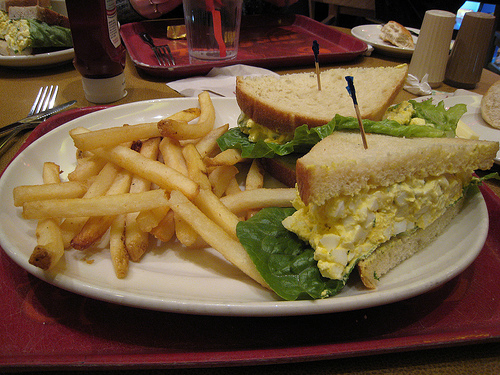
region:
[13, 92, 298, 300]
a pile of fries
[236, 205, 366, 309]
green leaf sticking out of the sandwich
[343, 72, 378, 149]
toothpick sticking in the bread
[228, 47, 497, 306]
two halves of a sandwich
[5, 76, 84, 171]
a fork and a knife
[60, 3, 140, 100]
bottle of ketchup on the table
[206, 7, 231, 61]
straw in the grass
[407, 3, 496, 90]
salt and pepper shakers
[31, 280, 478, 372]
shadow from the plate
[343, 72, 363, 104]
top of the toothpick is blue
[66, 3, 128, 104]
Plastic bottle of ketchup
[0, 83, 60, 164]
Silver fork on underneath knife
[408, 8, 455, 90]
Salt shaker on table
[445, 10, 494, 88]
Pepper shaker on table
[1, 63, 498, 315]
White plate with sandwich and fries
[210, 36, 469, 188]
Egg salad sandwich with toothpick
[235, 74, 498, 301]
Egg salad sandwich with toothpick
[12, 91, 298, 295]
Pile of french fries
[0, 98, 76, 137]
Silver butter knife on top of fork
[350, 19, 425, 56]
White plate with bread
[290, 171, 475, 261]
egg inside sandwich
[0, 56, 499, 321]
sandwiches on white dish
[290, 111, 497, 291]
the sandwich is triangle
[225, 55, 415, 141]
the sandwich is triangle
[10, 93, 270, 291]
french fries on white dish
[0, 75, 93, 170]
fork and knife on side a dish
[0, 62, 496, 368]
white dish on a tray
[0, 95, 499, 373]
tray is color red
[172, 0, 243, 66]
a glass on a tray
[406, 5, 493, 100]
bottles of salt and pepper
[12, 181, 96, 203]
french fry next to french fry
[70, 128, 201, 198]
french fry next to french fry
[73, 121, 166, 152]
french fry next to french fry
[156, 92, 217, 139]
french fry next to french fry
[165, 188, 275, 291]
french fry next to french fry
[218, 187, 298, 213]
french fry next to french fry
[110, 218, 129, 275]
french fry next to french fry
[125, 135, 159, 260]
french fry next to french fry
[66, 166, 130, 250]
french fry next to french fry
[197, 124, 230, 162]
french fry next to french fry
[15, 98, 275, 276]
french fries on plate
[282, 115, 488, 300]
a egge sandwich on plate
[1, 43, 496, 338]
food on a white plate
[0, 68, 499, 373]
white plate on red tray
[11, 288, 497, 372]
the shadow of the plate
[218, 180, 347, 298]
a green spainch leaf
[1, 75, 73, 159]
a silver fork and a knife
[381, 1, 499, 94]
a salt and pepper shaker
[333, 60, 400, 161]
a tooth pick in a sandwich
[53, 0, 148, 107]
a bottle of ketchup